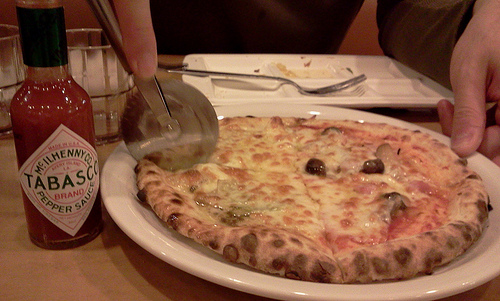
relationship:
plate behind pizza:
[183, 53, 454, 106] [130, 110, 495, 283]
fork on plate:
[158, 63, 367, 96] [183, 53, 454, 106]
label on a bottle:
[15, 119, 101, 239] [9, 0, 104, 251]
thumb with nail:
[447, 51, 485, 159] [449, 127, 473, 148]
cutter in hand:
[85, 0, 219, 172] [103, 0, 162, 82]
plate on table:
[108, 99, 498, 284] [1, 51, 483, 297]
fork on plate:
[158, 63, 367, 96] [177, 50, 482, 109]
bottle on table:
[9, 0, 104, 251] [1, 242, 206, 297]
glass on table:
[66, 27, 140, 145] [2, 130, 285, 299]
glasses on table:
[2, 18, 31, 144] [2, 130, 285, 299]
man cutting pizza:
[114, 1, 499, 157] [130, 110, 495, 283]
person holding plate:
[114, 1, 498, 159] [100, 102, 499, 300]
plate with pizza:
[100, 102, 499, 300] [130, 110, 495, 283]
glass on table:
[83, 46, 150, 129] [10, 244, 117, 294]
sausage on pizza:
[290, 148, 388, 188] [148, 102, 479, 299]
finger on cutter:
[103, 2, 163, 90] [113, 81, 231, 171]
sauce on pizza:
[10, 1, 105, 251] [133, 87, 498, 299]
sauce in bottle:
[10, 1, 105, 251] [8, 14, 109, 257]